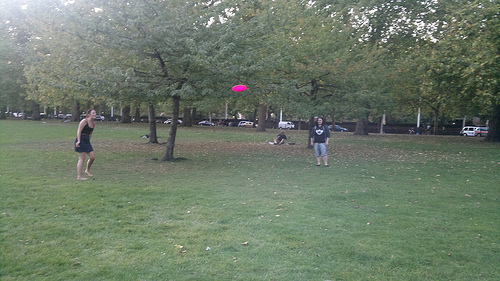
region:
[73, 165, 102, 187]
the girl is barefooted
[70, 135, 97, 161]
the girl is wearing shorts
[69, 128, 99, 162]
the girl's shorts are blue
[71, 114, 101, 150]
the girl is wearing a tank top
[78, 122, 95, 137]
the girl's tank top is black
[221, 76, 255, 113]
the frisbee is red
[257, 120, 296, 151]
the person is sitting on the ground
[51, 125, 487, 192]
the leaves are on the ground under the tree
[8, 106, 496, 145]
the cars are parked in the parking lot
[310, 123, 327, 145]
the man has a black t-shirt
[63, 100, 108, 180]
woman wearing black shirt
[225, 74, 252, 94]
pink frisbee in the air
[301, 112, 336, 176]
man wearing a shirt with logo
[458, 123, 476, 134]
white van in the background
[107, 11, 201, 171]
two green trees beside the woman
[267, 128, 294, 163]
person sitting on the ground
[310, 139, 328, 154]
gray shorts man is wearing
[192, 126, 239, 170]
leaves on the ground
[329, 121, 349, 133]
blue car in background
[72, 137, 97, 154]
jean shorts on the woman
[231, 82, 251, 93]
The Frisbee is pink.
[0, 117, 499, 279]
The ground is covered with grass.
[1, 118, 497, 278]
The grass is green.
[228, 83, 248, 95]
The Frisbee is in the air.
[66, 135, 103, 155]
The shorts are blue.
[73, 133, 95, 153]
The woman is wearing shorts.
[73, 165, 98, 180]
The woman is barefoot.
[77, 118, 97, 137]
The woman is wearing a tank top.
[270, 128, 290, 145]
The person is sitting down.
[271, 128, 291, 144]
The person is far in the distance.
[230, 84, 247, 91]
a pink Frisbee in the air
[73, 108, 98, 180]
a barefoot girl in a park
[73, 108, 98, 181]
a girl in a black tank top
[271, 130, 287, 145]
a person sitting in the grass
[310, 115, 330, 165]
a person in a black shirt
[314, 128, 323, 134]
a white symbol on a black shirt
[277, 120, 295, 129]
a white van by a park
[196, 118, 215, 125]
a car by a park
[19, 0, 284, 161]
a tree in a park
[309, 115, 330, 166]
a person with black shoes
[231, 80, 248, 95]
a pink colour frisbee flying in the air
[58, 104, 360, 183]
a lady and the man standing in the lawn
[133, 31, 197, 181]
a tree with many branches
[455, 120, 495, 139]
a car parked under the tree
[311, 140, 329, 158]
a man is weraing a blue colour half-trouser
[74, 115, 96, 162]
a black colour dress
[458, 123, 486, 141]
a white colour car parked in the place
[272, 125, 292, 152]
a person sitting in the lawn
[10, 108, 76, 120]
many card parked under the tree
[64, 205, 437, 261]
a green lawn